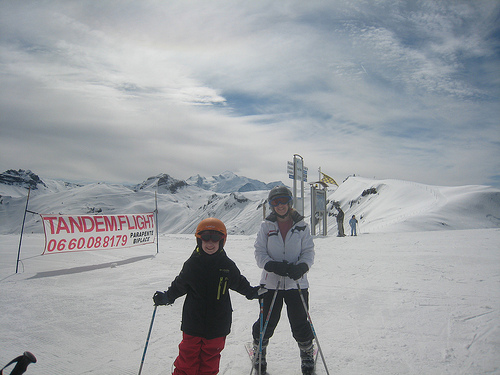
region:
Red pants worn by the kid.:
[181, 328, 221, 373]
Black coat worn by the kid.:
[169, 255, 240, 334]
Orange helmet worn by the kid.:
[190, 215, 231, 232]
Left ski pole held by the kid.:
[142, 290, 158, 374]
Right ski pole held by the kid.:
[256, 292, 267, 372]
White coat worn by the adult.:
[258, 215, 310, 294]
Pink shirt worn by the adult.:
[273, 223, 291, 235]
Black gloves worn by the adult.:
[263, 257, 304, 282]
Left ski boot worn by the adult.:
[248, 331, 275, 373]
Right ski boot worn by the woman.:
[292, 330, 316, 373]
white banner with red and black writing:
[42, 210, 153, 256]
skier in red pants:
[170, 333, 227, 373]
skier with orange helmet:
[194, 215, 228, 244]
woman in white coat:
[253, 212, 314, 289]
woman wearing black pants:
[253, 287, 315, 342]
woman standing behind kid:
[249, 185, 323, 374]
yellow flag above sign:
[319, 171, 339, 191]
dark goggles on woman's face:
[269, 196, 294, 207]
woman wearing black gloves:
[263, 257, 308, 280]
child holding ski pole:
[136, 298, 161, 373]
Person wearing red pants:
[151, 352, 236, 371]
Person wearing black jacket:
[173, 254, 256, 319]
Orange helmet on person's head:
[196, 214, 232, 249]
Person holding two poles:
[130, 268, 265, 371]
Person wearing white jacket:
[259, 211, 335, 287]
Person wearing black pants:
[250, 280, 336, 356]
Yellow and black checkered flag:
[311, 162, 355, 225]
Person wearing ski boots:
[235, 320, 340, 367]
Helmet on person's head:
[247, 175, 308, 238]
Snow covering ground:
[50, 235, 499, 337]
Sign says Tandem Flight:
[12, 190, 162, 271]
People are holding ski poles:
[137, 181, 330, 373]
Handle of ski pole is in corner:
[0, 351, 42, 373]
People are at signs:
[331, 202, 363, 239]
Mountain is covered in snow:
[0, 167, 498, 373]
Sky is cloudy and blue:
[0, 0, 499, 187]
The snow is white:
[0, 170, 498, 373]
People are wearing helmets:
[132, 185, 337, 372]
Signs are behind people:
[286, 148, 331, 236]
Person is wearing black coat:
[146, 215, 268, 373]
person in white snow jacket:
[242, 162, 330, 374]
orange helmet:
[174, 216, 230, 276]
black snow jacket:
[164, 253, 260, 373]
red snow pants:
[162, 325, 215, 374]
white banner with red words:
[24, 211, 161, 275]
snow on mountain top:
[69, 185, 249, 220]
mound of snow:
[416, 191, 498, 269]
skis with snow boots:
[239, 340, 346, 374]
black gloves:
[260, 266, 324, 292]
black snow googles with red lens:
[253, 197, 326, 211]